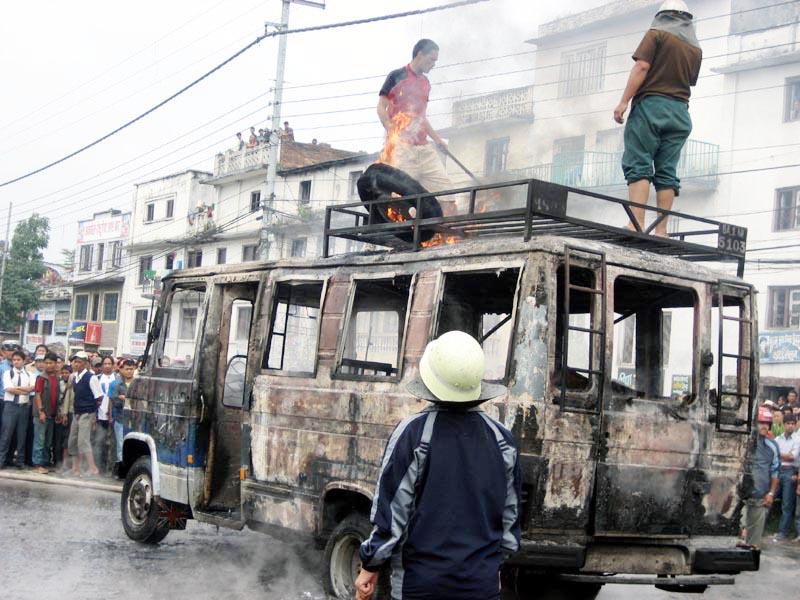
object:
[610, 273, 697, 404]
window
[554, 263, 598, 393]
window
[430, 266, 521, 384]
window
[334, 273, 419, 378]
window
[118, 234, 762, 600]
car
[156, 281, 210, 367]
window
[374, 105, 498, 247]
fire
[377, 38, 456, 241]
man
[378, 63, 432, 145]
shirt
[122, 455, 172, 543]
tire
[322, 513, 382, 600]
tire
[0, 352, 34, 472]
person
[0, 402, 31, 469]
pants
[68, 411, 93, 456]
pants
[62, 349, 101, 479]
person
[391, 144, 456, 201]
shorts